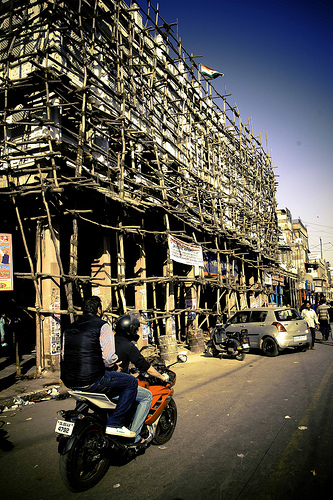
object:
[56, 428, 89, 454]
rear fender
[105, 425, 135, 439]
sneaker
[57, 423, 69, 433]
lettering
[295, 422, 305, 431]
debris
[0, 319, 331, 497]
street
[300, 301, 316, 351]
man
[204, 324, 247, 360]
scooter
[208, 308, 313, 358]
suv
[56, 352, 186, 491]
bike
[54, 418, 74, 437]
license plate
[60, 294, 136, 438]
guy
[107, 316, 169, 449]
guy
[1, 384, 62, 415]
curb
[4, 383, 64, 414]
trash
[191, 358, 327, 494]
road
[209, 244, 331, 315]
poles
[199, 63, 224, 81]
flag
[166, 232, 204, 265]
banner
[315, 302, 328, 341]
person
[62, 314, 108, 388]
vest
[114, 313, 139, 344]
helmet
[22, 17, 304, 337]
structure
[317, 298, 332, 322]
shirt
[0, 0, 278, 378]
building